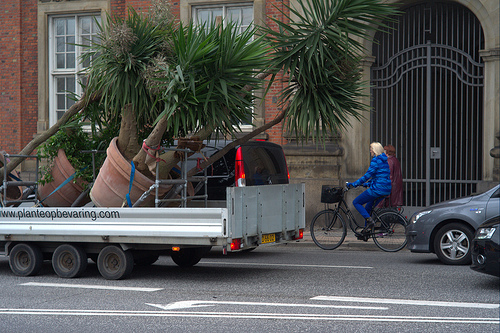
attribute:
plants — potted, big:
[4, 4, 382, 205]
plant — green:
[86, 39, 342, 176]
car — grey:
[404, 171, 499, 256]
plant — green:
[83, 5, 401, 210]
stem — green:
[212, 77, 229, 103]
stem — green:
[0, 75, 92, 187]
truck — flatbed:
[0, 144, 308, 279]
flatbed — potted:
[3, 176, 323, 248]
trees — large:
[6, 0, 380, 195]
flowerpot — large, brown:
[81, 132, 162, 209]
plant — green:
[189, 42, 279, 94]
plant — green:
[159, 57, 236, 169]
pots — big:
[1, 117, 208, 202]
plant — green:
[278, 90, 326, 140]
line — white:
[21, 280, 166, 293]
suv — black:
[148, 128, 286, 260]